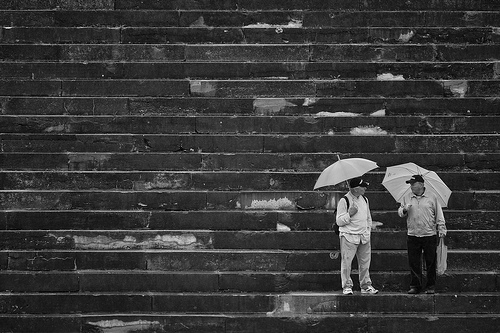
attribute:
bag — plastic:
[434, 236, 451, 279]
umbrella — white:
[383, 166, 452, 213]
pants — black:
[406, 236, 439, 290]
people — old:
[301, 147, 468, 301]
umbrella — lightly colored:
[382, 160, 455, 210]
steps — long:
[51, 6, 493, 328]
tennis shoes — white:
[337, 281, 407, 306]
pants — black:
[406, 227, 439, 291]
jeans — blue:
[332, 230, 384, 299]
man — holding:
[310, 150, 383, 299]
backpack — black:
[327, 187, 357, 239]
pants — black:
[388, 237, 448, 282]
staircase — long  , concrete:
[1, 15, 367, 332]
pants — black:
[400, 235, 442, 294]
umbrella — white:
[382, 161, 452, 213]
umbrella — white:
[313, 150, 379, 191]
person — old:
[326, 171, 387, 296]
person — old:
[399, 168, 453, 295]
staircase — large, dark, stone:
[4, 3, 317, 326]